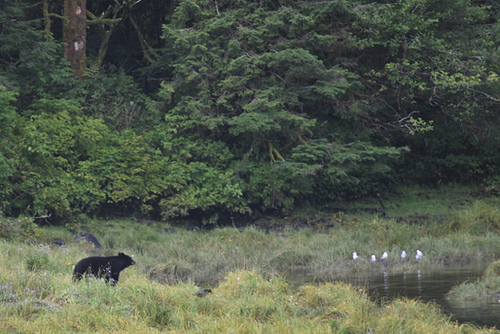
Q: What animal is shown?
A: Bear.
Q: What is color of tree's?
A: Green.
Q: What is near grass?
A: Water.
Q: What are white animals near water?
A: Birds.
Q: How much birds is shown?
A: Five.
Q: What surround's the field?
A: Tree's.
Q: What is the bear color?
A: Black.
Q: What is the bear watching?
A: Birds.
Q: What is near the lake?
A: A flock of birds.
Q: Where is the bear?
A: Near the lake.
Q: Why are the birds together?
A: They flock together.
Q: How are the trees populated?
A: Heavily.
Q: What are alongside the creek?
A: Birds.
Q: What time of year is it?
A: Summertime.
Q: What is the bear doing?
A: Looking at the birds.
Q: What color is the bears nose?
A: Brown.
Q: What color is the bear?
A: Black.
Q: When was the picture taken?
A: Daytime.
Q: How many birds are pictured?
A: Five.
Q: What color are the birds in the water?
A: White.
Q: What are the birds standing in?
A: Water.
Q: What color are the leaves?
A: Green.